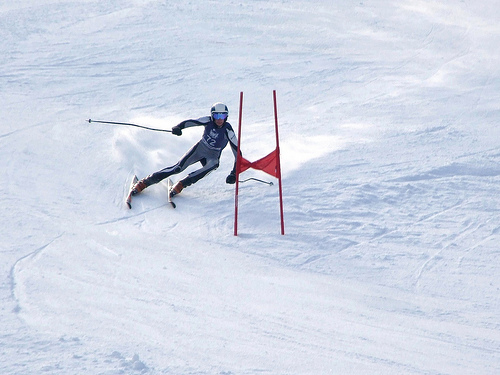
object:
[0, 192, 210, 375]
markings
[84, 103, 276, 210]
no object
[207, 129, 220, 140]
logo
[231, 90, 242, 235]
pole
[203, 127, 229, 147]
chest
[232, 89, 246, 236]
pole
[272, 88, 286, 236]
pole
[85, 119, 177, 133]
pole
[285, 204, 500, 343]
tracks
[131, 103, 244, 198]
woman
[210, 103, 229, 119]
helmet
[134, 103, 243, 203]
man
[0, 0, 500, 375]
snow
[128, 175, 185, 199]
shoes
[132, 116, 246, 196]
snowsuit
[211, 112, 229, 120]
blue goggles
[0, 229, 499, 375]
ground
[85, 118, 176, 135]
ski pole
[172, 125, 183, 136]
hand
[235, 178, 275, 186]
ski pole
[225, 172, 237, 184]
hand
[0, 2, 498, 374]
hill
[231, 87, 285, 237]
two poles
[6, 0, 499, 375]
slope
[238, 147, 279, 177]
flag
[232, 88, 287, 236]
poles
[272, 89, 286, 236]
post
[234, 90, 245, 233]
post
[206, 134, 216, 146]
number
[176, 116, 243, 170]
shirt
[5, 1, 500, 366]
slalom